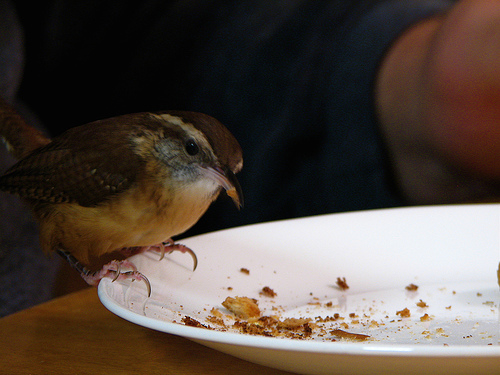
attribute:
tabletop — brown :
[2, 255, 105, 372]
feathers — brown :
[31, 133, 119, 233]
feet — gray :
[68, 236, 198, 296]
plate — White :
[103, 181, 499, 368]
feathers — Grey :
[119, 116, 188, 171]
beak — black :
[103, 112, 258, 222]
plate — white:
[93, 199, 499, 374]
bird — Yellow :
[4, 98, 260, 290]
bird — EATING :
[7, 62, 250, 319]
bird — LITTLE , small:
[5, 106, 245, 294]